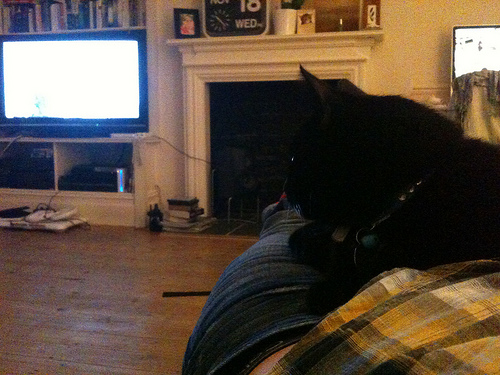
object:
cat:
[273, 59, 498, 312]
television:
[0, 33, 154, 138]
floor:
[0, 220, 258, 375]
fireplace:
[205, 77, 363, 228]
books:
[170, 196, 195, 206]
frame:
[173, 7, 202, 38]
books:
[0, 1, 150, 33]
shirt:
[264, 261, 497, 374]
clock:
[200, 0, 272, 40]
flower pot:
[271, 7, 298, 37]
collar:
[334, 129, 475, 252]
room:
[3, 0, 499, 374]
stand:
[0, 134, 167, 223]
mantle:
[164, 27, 384, 73]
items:
[0, 200, 88, 235]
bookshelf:
[0, 0, 170, 227]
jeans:
[198, 192, 338, 375]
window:
[453, 23, 499, 80]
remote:
[0, 206, 30, 218]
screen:
[1, 38, 141, 123]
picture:
[180, 15, 194, 37]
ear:
[294, 63, 344, 125]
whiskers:
[282, 197, 293, 237]